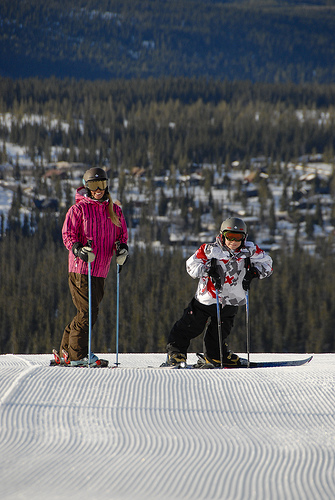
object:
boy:
[165, 215, 275, 365]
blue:
[89, 283, 91, 310]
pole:
[114, 258, 121, 367]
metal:
[87, 239, 93, 248]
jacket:
[62, 187, 128, 276]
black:
[81, 254, 88, 260]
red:
[207, 281, 212, 290]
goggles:
[83, 176, 113, 192]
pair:
[223, 229, 244, 241]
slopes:
[0, 341, 335, 500]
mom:
[48, 163, 131, 369]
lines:
[0, 363, 37, 409]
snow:
[0, 353, 334, 500]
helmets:
[218, 215, 250, 238]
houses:
[42, 166, 68, 180]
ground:
[0, 353, 335, 500]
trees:
[157, 185, 171, 219]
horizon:
[0, 348, 335, 359]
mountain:
[0, 0, 335, 75]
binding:
[70, 239, 95, 263]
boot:
[164, 341, 189, 366]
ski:
[191, 351, 316, 368]